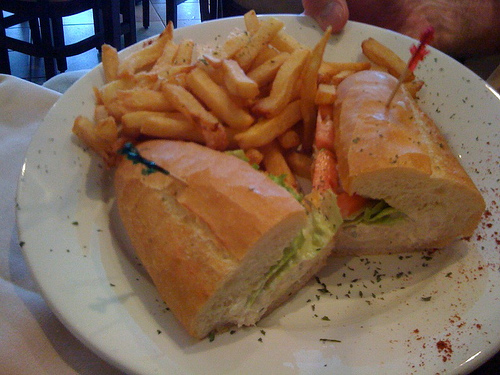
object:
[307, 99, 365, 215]
tomato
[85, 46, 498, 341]
small baguette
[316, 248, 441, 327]
herbs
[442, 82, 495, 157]
spices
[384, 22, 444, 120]
toothpick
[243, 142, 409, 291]
lettuce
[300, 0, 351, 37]
thumb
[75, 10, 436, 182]
french fries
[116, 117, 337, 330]
sandwich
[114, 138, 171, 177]
toothpick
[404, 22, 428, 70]
tag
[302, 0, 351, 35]
person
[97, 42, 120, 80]
fries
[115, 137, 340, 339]
bread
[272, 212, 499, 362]
seasoning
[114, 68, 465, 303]
meal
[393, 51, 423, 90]
toothpick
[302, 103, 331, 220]
red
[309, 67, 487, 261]
sandwich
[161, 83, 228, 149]
fries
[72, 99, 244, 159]
pile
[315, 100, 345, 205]
slice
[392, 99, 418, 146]
toothpick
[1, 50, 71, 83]
chairs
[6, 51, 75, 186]
restaurant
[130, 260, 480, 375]
plate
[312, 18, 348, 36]
hand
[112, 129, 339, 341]
food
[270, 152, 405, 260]
half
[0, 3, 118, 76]
chairs